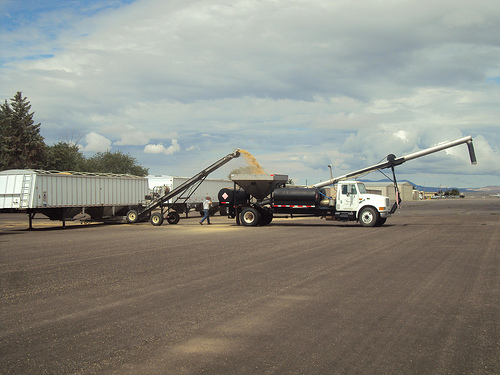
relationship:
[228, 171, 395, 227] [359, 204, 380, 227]
truck has wheels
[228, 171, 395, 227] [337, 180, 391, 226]
truck has a white cab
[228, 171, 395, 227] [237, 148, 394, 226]
truck being loaded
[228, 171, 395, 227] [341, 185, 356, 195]
truck has a side window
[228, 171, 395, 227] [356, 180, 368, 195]
truck has a windshield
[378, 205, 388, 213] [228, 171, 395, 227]
lights on truck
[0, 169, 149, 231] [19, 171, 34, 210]
trailer has a metal ladder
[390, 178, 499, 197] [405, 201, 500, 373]
mountain beyond road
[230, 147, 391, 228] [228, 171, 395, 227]
loading a truck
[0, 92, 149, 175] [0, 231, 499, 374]
trees along road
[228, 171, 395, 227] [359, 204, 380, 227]
truck has a front wheel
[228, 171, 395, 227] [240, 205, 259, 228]
truck has rear wheels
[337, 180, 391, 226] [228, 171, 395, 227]
cab of truck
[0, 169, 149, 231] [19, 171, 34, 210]
trailer has a ladder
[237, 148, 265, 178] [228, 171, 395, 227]
sand loaded on truck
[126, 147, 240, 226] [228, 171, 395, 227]
conveyor over truck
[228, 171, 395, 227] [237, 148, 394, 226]
lorry carries heavy loads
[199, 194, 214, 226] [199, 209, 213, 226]
man in blue jeans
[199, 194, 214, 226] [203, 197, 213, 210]
man has white shirt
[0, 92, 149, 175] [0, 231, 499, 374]
green trees on side of pavement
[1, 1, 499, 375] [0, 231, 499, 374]
sunny day on pavement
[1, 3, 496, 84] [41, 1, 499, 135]
blue sky with clouds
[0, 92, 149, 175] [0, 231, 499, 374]
trees on roadside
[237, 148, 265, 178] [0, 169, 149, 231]
sand in trailer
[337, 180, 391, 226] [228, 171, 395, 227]
cab white on truck